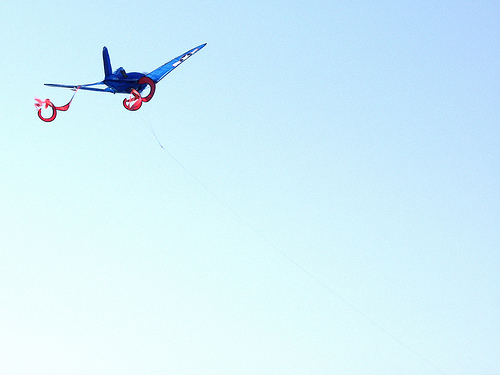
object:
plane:
[36, 41, 208, 125]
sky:
[0, 1, 499, 374]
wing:
[146, 43, 208, 82]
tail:
[102, 46, 114, 83]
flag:
[33, 98, 71, 123]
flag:
[123, 93, 145, 111]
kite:
[43, 43, 206, 94]